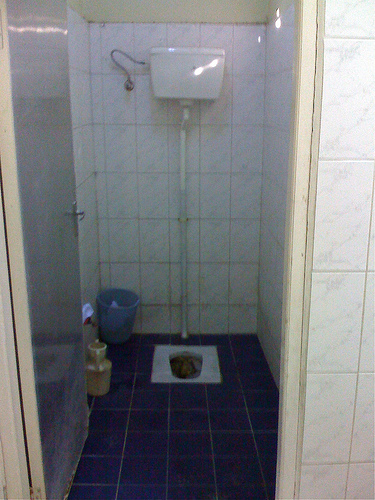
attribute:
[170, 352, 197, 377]
wastes — part , some 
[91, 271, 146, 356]
bin — part , litter 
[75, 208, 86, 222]
handle — part , door 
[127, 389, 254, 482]
floor — part , toilet 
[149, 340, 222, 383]
toilet — part 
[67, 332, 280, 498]
floor — part , toilet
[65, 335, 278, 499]
ground — tile, blue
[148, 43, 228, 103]
tank — white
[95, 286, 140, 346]
basket — blue, light blue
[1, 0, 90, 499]
door — white, open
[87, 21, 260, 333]
wall — tiled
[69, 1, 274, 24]
ceiling — white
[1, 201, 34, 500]
door edge — white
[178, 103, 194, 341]
pipe — white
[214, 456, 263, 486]
tile — blue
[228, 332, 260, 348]
tile — blue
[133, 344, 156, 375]
tile — blue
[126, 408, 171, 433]
tile — blue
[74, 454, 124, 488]
tile — blue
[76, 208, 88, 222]
handle — silver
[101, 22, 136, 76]
tile — cream, rectangular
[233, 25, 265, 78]
tile — cream, rectangular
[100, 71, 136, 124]
tile — cream, rectangular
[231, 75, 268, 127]
tile — cream, rectangular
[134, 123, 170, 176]
tile — cream, rec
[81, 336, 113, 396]
jug — cream colored